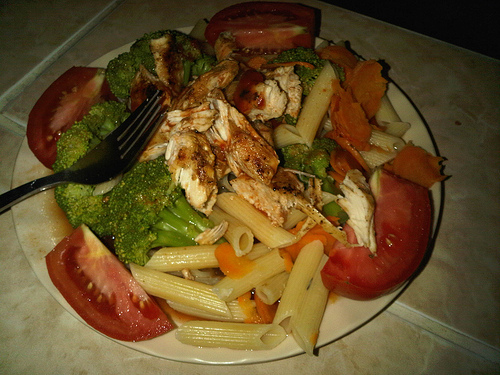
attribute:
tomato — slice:
[333, 172, 442, 308]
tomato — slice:
[39, 228, 179, 347]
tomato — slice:
[30, 70, 123, 147]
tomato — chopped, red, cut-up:
[319, 166, 434, 302]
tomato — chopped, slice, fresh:
[202, 0, 319, 57]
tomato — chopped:
[24, 65, 121, 172]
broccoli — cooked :
[52, 97, 224, 267]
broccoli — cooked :
[278, 110, 348, 224]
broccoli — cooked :
[270, 46, 347, 98]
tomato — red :
[318, 174, 440, 301]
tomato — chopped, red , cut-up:
[42, 224, 170, 341]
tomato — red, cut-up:
[348, 193, 405, 269]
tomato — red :
[42, 229, 187, 366]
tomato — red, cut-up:
[330, 178, 430, 295]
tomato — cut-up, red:
[47, 227, 170, 349]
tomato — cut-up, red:
[27, 65, 107, 167]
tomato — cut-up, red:
[207, 6, 322, 51]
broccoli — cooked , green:
[104, 25, 214, 107]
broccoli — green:
[108, 159, 223, 265]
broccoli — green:
[276, 131, 339, 174]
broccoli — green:
[265, 45, 345, 90]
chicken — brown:
[174, 90, 275, 207]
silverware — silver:
[4, 76, 178, 233]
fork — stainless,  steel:
[4, 81, 164, 218]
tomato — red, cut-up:
[37, 217, 178, 346]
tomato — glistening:
[38, 225, 178, 339]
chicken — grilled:
[137, 58, 317, 213]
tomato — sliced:
[32, 13, 413, 308]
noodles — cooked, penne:
[150, 227, 348, 360]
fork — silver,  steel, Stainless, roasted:
[0, 90, 172, 212]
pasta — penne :
[123, 184, 363, 357]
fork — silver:
[26, 58, 181, 224]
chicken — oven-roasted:
[139, 60, 310, 232]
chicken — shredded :
[149, 67, 329, 208]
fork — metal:
[24, 46, 190, 232]